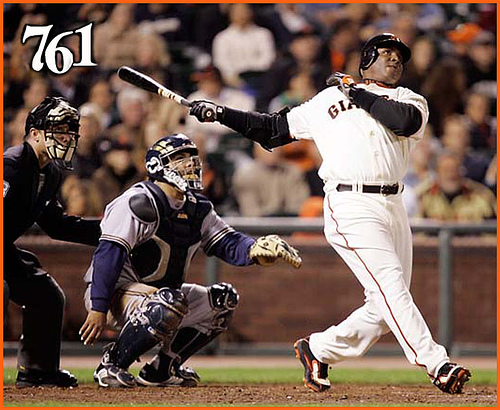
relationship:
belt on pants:
[328, 183, 401, 195] [309, 179, 450, 380]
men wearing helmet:
[1, 96, 106, 389] [24, 95, 80, 130]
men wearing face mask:
[1, 96, 106, 389] [44, 121, 79, 167]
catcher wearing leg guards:
[78, 131, 303, 390] [168, 278, 239, 382]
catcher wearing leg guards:
[78, 131, 303, 390] [99, 288, 189, 389]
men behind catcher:
[1, 96, 106, 389] [78, 131, 303, 390]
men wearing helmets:
[1, 96, 106, 389] [20, 95, 81, 171]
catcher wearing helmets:
[78, 131, 305, 388] [144, 130, 206, 194]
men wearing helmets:
[188, 30, 471, 397] [355, 30, 410, 79]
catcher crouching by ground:
[78, 131, 305, 388] [4, 361, 482, 404]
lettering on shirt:
[334, 83, 389, 113] [284, 79, 428, 184]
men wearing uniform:
[1, 96, 106, 389] [0, 141, 102, 370]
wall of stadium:
[234, 231, 497, 348] [104, 9, 497, 289]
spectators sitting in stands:
[126, 3, 315, 120] [3, 7, 498, 248]